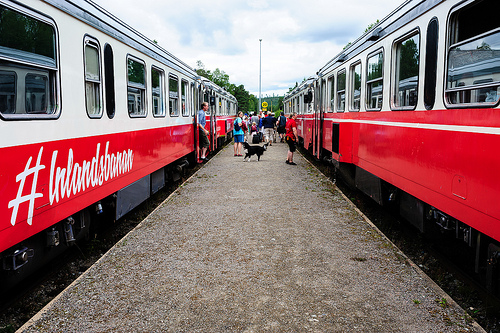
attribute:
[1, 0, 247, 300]
train — red, white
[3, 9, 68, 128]
window — red , white 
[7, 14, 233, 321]
train — red, white